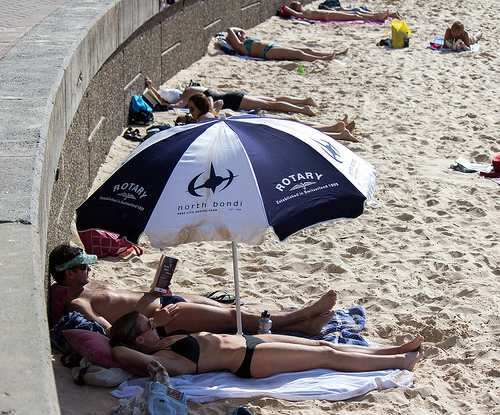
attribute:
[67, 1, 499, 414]
sand — visisble, clear, light brown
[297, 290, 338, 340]
feet — crossed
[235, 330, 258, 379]
bikini bottom — black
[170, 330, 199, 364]
bikini top — black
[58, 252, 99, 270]
visor — green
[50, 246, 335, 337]
man — sunbathing, enjoying beach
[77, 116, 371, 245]
umbrella — blue, white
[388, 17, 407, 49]
bag — yellow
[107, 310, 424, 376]
woman — sunbathing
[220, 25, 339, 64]
woman — suntanning, sunbathing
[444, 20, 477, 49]
man — sunbathing, suntanning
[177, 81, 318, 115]
woman — sunbathing, suntanning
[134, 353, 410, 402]
towel — white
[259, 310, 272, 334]
bottle — here